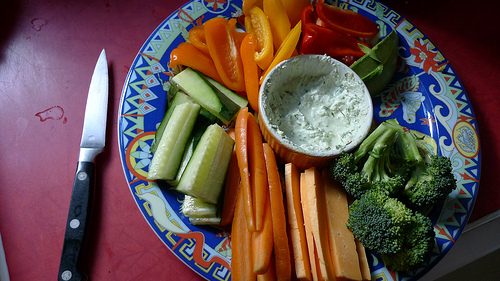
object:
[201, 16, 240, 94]
peppers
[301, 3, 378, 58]
red pepper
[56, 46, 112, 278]
knife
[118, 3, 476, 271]
plate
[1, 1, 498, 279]
table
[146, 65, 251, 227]
cucumbers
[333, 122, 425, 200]
broccoli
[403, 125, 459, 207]
broccoli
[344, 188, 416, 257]
broccoli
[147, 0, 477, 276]
appetizer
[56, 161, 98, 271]
handle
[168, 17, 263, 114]
orange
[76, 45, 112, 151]
blade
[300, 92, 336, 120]
dressing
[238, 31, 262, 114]
pepper